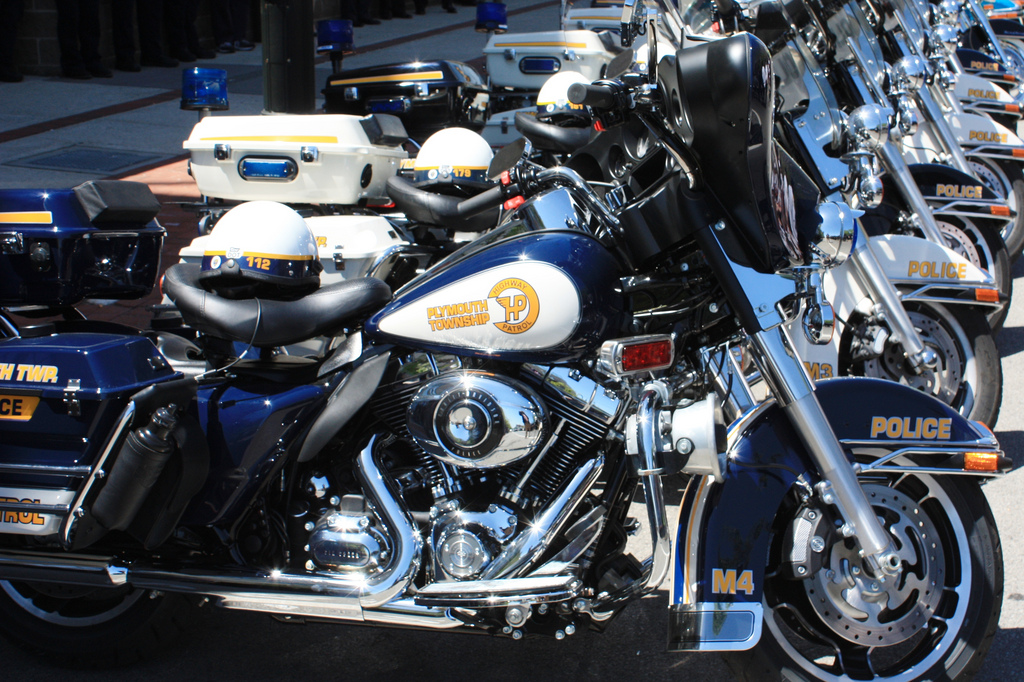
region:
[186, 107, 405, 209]
bike has a carrage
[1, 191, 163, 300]
bike has a carrage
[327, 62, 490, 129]
bike has a carrage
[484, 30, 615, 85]
bike has a carrage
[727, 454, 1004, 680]
bike has a tire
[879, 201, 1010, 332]
bike has a tire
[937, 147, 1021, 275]
bike has a tire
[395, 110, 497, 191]
helmet on the motorcycle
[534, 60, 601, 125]
helmet on the motorcycle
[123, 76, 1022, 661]
Motorcycle is blue and white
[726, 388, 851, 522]
A person eating a orange.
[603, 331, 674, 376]
Light reflector on the motorcycle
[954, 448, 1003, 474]
Light reflector on the motorcycle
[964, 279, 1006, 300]
Light reflector on the motorcycle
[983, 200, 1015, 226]
Light reflector on the motorcycle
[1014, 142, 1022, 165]
Light reflector on the motorcycle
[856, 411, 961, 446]
police sign on the bike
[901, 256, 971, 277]
police sign on the bike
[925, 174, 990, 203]
police sign on the bike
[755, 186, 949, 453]
a motorcycle parked in a row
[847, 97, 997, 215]
a motorcycle parked in a row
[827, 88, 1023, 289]
a motorcycle parked in a row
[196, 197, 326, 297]
a helmet is on the motorcycle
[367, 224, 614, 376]
the gas tank is on the motorcycle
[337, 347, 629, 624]
the motor is made of chrome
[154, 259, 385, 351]
the seat is made of plastic